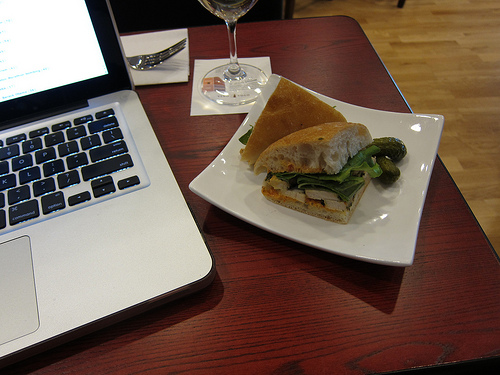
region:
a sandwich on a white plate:
[190, 70, 445, 273]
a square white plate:
[190, 70, 445, 265]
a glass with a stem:
[203, 0, 258, 110]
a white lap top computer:
[3, 0, 209, 360]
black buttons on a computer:
[0, 110, 140, 225]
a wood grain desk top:
[258, 281, 498, 371]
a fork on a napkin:
[127, 28, 187, 80]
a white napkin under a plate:
[125, 26, 191, 86]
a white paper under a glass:
[191, 52, 269, 108]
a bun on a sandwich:
[261, 126, 371, 178]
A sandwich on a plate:
[197, 70, 472, 290]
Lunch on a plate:
[203, 70, 469, 268]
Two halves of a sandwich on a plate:
[206, 56, 426, 255]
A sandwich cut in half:
[228, 80, 429, 230]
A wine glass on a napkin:
[192, 4, 276, 104]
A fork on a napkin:
[123, 29, 190, 84]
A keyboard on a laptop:
[2, 112, 212, 324]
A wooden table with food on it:
[139, 15, 484, 373]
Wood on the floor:
[382, 13, 495, 132]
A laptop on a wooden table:
[0, 3, 228, 372]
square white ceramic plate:
[187, 68, 446, 278]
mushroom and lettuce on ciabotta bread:
[261, 117, 372, 216]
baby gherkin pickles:
[361, 110, 409, 190]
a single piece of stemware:
[179, 4, 271, 106]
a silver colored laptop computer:
[0, 0, 211, 360]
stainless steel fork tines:
[118, 35, 190, 75]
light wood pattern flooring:
[313, 0, 498, 221]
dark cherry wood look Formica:
[138, 23, 496, 373]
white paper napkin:
[125, 31, 195, 86]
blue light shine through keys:
[2, 105, 142, 233]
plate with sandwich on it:
[191, 70, 451, 269]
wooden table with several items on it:
[225, 283, 499, 364]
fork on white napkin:
[127, 27, 194, 88]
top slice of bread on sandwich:
[254, 121, 374, 166]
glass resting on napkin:
[188, 3, 273, 119]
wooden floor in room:
[447, 2, 494, 162]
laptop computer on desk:
[0, 0, 214, 371]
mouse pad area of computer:
[0, 233, 47, 348]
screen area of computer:
[2, 0, 122, 101]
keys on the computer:
[0, 112, 147, 215]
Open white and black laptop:
[0, 0, 215, 367]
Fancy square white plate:
[187, 73, 444, 268]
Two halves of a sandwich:
[240, 76, 407, 226]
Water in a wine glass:
[197, 0, 269, 106]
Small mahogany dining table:
[0, 14, 499, 373]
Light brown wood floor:
[290, 0, 496, 255]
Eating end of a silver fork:
[122, 36, 186, 71]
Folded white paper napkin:
[120, 25, 192, 85]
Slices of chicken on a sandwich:
[263, 173, 346, 214]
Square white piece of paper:
[187, 55, 272, 120]